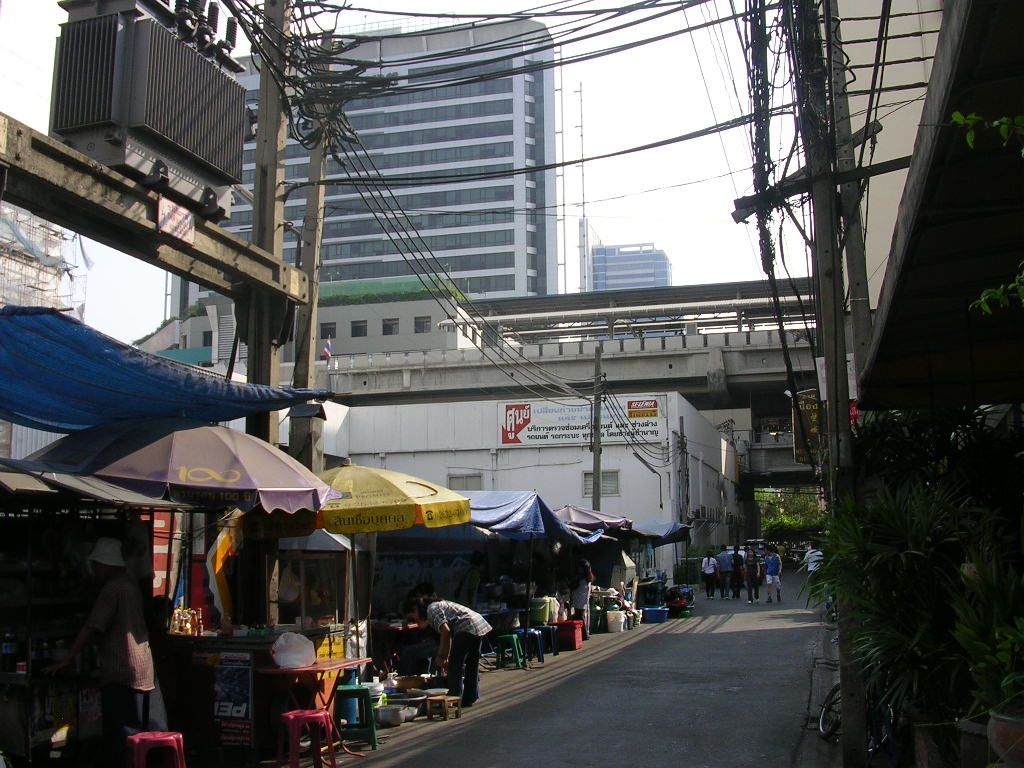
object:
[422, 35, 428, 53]
wall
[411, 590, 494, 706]
woman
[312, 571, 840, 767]
street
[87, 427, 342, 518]
umbrella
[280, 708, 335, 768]
stool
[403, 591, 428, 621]
head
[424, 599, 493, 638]
shirt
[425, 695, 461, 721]
box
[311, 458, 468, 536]
umbrella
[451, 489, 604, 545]
tent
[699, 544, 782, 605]
people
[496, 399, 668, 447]
sign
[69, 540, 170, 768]
man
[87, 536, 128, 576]
hat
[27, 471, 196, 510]
awning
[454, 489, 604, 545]
umbrella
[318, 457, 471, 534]
canopy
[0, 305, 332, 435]
tarp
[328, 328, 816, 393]
bridge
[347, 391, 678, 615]
building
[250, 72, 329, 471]
pole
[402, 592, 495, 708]
person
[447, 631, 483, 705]
pants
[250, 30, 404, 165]
wire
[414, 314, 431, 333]
window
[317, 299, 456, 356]
wall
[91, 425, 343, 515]
patio umbrella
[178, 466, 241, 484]
pattern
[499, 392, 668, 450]
banner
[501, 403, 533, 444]
symbols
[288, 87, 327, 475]
pole